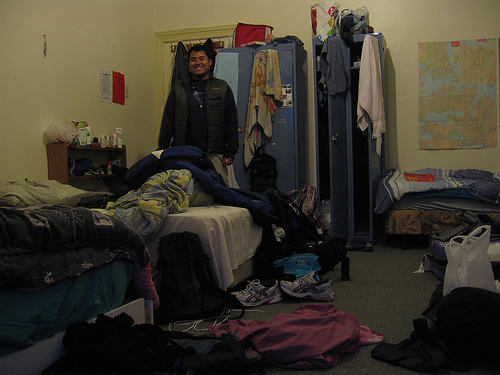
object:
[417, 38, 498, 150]
map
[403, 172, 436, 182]
book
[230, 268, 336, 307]
shoe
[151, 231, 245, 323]
back pack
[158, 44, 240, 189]
man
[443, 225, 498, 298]
plastic bag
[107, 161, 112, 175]
tube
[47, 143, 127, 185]
brown shelf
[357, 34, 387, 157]
white towel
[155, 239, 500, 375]
floor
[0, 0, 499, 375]
bedroom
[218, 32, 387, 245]
locker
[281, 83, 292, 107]
sticker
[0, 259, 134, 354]
blanket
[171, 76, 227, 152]
vest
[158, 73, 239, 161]
jacket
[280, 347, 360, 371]
shadow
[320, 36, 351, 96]
towels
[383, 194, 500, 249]
bed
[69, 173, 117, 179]
shelf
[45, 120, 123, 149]
items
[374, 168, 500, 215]
comforter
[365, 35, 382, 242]
door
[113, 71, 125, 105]
paper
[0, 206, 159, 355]
sofa top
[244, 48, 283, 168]
clothing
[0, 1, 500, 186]
wall